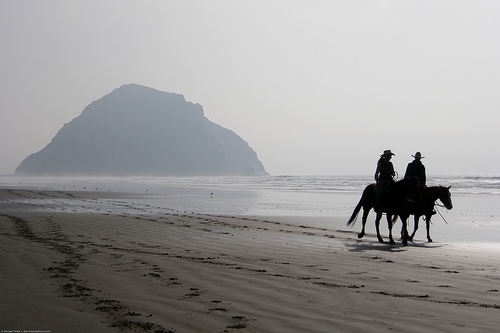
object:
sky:
[3, 7, 269, 92]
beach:
[2, 200, 332, 332]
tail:
[342, 198, 365, 227]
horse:
[346, 179, 424, 246]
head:
[399, 175, 425, 198]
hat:
[382, 148, 395, 157]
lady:
[374, 149, 397, 185]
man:
[407, 153, 429, 183]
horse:
[405, 184, 454, 240]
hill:
[15, 77, 271, 178]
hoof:
[357, 232, 365, 240]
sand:
[2, 186, 162, 220]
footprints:
[124, 201, 154, 212]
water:
[270, 177, 318, 187]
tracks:
[11, 214, 35, 238]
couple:
[376, 148, 436, 189]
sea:
[218, 168, 499, 204]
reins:
[435, 200, 443, 213]